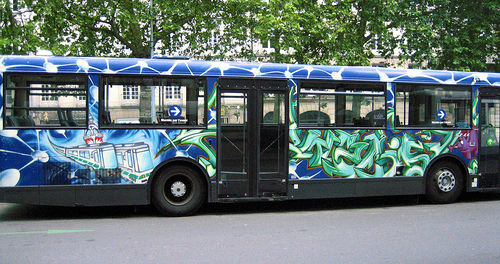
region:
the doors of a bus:
[215, 79, 290, 199]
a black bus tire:
[151, 159, 208, 213]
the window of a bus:
[97, 72, 207, 129]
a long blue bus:
[1, 51, 499, 218]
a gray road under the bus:
[0, 196, 499, 262]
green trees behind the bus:
[0, 0, 499, 74]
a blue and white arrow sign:
[166, 103, 182, 118]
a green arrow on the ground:
[0, 224, 95, 239]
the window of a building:
[119, 82, 142, 100]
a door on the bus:
[478, 84, 499, 189]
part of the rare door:
[224, 110, 249, 175]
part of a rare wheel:
[171, 190, 199, 215]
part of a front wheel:
[433, 173, 459, 200]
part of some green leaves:
[234, 22, 341, 49]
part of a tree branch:
[115, 35, 137, 52]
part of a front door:
[478, 120, 493, 156]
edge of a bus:
[328, 191, 391, 203]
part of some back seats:
[3, 115, 32, 128]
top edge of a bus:
[391, 67, 461, 79]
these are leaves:
[156, 5, 465, 50]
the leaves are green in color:
[153, 0, 454, 44]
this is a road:
[161, 216, 442, 259]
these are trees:
[0, 0, 492, 55]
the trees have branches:
[3, 0, 225, 53]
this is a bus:
[3, 58, 484, 195]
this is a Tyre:
[149, 165, 201, 212]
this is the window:
[98, 74, 208, 125]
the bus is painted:
[45, 130, 475, 180]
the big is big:
[0, 55, 492, 197]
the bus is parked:
[13, 42, 457, 222]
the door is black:
[203, 87, 315, 223]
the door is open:
[203, 67, 316, 194]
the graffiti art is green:
[291, 115, 466, 200]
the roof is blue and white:
[10, 43, 494, 93]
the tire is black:
[143, 162, 216, 208]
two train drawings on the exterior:
[41, 131, 194, 203]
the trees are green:
[163, 3, 244, 53]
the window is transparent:
[98, 82, 223, 154]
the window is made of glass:
[88, 75, 240, 162]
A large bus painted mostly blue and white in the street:
[1, 58, 499, 214]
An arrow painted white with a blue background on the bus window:
[164, 102, 189, 127]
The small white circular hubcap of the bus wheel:
[163, 171, 194, 201]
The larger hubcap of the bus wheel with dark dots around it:
[433, 165, 458, 192]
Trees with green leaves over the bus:
[1, 0, 498, 70]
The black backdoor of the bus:
[216, 80, 291, 201]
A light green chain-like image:
[286, 125, 428, 176]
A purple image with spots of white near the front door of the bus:
[450, 123, 482, 160]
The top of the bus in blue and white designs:
[0, 55, 498, 85]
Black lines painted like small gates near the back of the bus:
[41, 162, 123, 184]